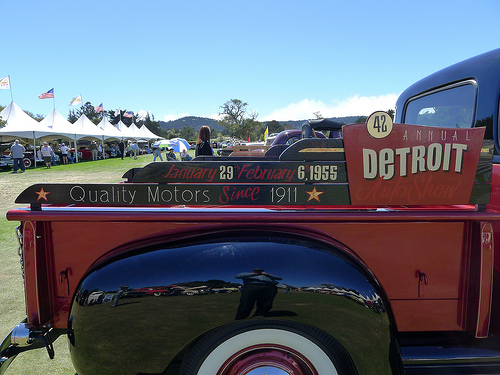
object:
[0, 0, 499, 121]
sky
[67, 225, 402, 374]
fender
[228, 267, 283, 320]
reflection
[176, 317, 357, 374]
tire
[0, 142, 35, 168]
antique cars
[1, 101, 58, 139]
tents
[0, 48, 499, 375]
truck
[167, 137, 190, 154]
umbrella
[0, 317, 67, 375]
bumper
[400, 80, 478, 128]
window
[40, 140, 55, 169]
man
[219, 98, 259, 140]
tree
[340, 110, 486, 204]
sign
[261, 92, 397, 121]
clouds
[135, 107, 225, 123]
clouds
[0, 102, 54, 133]
roof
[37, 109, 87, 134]
roof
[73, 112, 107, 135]
roof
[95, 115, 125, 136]
roof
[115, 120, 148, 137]
roof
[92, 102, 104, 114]
flag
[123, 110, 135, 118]
flag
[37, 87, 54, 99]
flag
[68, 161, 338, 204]
words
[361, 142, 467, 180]
detroit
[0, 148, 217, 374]
ground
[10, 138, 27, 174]
people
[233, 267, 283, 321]
man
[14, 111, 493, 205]
wood railing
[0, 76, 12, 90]
flags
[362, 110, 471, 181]
gold and white